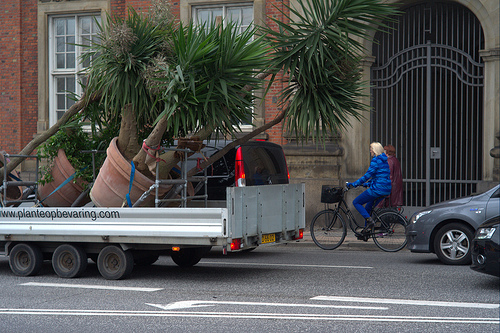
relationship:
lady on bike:
[347, 140, 393, 232] [312, 179, 410, 253]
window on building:
[190, 3, 255, 133] [2, 3, 498, 228]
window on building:
[40, 5, 105, 129] [2, 3, 498, 228]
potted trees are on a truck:
[14, 12, 365, 190] [0, 182, 307, 281]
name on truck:
[0, 208, 125, 220] [2, 135, 318, 296]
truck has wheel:
[0, 182, 307, 281] [92, 244, 132, 279]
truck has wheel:
[0, 182, 307, 281] [49, 239, 84, 279]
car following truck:
[404, 183, 500, 266] [0, 182, 307, 281]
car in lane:
[404, 183, 500, 266] [2, 249, 499, 316]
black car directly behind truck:
[10, 138, 293, 256] [0, 173, 307, 278]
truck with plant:
[0, 173, 307, 278] [150, 0, 403, 180]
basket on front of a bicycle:
[318, 184, 344, 203] [311, 179, 406, 250]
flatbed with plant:
[3, 176, 323, 248] [150, 0, 403, 180]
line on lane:
[21, 280, 166, 293] [2, 243, 498, 333]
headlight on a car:
[472, 228, 495, 246] [472, 215, 497, 284]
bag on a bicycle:
[319, 181, 346, 204] [309, 181, 410, 252]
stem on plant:
[0, 75, 92, 187] [92, 23, 267, 135]